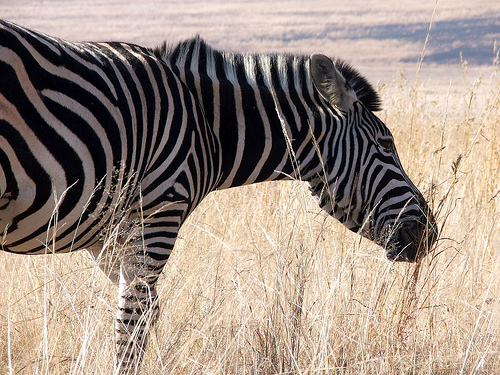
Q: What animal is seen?
A: Zebra.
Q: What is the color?
A: Black and white.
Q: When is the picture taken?
A: Daytime.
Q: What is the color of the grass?
A: Brown.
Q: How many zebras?
A: 1.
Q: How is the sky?
A: With clouds.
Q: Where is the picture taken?
A: On the Savannah.